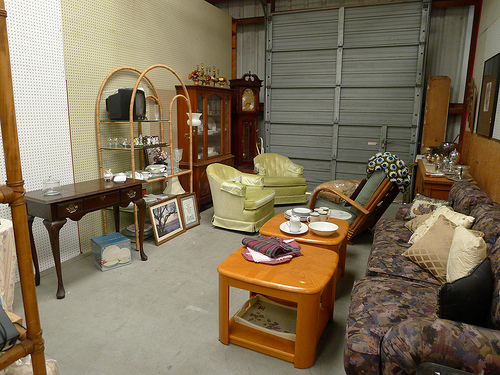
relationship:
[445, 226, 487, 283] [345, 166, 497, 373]
pillow on couch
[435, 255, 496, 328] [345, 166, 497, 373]
pillow on couch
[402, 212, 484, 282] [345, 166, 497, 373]
pillow on couch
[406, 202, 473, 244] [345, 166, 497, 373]
pillow on couch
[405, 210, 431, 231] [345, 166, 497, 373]
pillow on couch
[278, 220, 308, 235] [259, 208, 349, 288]
white dish on table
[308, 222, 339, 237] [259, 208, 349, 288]
bowl on table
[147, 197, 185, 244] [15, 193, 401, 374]
pictures on floor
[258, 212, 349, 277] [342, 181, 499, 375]
table in front of couch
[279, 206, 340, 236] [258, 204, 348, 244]
dishes on table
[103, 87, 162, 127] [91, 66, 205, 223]
tv on shelf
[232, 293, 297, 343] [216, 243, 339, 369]
tray under table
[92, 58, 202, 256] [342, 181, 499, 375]
shelf across couch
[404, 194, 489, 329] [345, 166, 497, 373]
pillows on couch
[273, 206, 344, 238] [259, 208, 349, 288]
dishes on table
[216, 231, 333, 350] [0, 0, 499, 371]
table in room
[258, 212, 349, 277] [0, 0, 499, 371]
table in room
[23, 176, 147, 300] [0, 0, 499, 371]
desk in room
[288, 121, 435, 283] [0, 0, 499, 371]
chair in room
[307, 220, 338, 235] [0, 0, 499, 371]
bowl in room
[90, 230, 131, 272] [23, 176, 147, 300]
box under desk